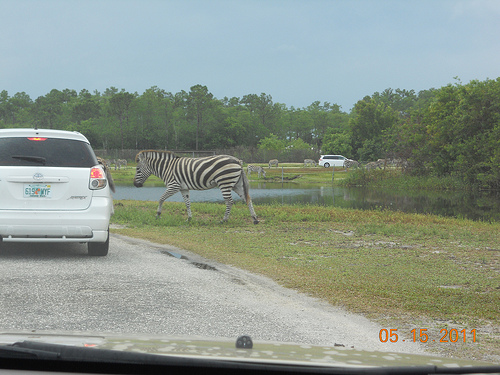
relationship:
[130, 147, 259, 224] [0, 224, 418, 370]
zebra walking to road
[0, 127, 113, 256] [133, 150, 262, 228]
car by zebra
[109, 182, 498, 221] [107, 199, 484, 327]
lake by grass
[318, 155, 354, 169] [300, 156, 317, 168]
car by animal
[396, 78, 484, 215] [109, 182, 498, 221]
tree by lake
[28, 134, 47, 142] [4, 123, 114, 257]
light of car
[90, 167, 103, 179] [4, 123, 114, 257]
brake light of car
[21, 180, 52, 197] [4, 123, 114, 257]
plates of car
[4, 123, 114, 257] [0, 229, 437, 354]
car on road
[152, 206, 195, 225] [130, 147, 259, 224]
feet of zebra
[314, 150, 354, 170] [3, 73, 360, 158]
car in front of trees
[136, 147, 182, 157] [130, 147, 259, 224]
mane of zebra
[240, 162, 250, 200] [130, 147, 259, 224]
tail of zebra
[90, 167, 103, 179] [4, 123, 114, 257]
brake light on back of car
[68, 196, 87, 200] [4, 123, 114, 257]
writing on car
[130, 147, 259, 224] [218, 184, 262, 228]
zebra has legs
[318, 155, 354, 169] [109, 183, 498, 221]
car across lake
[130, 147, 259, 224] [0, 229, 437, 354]
zebra by a road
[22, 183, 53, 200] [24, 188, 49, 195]
license plate with writing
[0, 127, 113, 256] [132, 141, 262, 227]
car next to a zebra